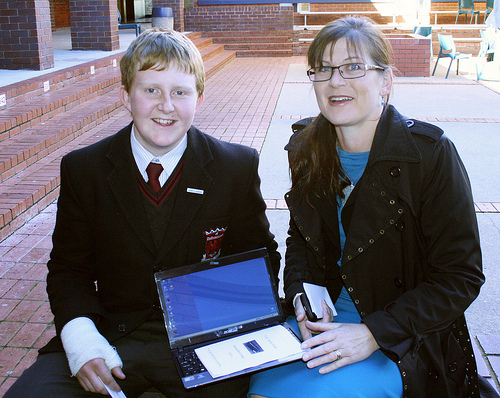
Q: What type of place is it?
A: It is a patio.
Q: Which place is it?
A: It is a patio.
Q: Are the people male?
A: No, they are both male and female.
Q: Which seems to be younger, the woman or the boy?
A: The boy is younger than the woman.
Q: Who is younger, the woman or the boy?
A: The boy is younger than the woman.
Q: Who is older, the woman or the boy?
A: The woman is older than the boy.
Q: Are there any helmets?
A: No, there are no helmets.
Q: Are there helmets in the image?
A: No, there are no helmets.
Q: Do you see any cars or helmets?
A: No, there are no helmets or cars.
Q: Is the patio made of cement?
A: Yes, the patio is made of cement.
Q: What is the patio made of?
A: The patio is made of concrete.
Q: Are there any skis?
A: No, there are no skis.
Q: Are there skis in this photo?
A: No, there are no skis.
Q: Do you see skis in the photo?
A: No, there are no skis.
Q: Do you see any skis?
A: No, there are no skis.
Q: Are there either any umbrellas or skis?
A: No, there are no skis or umbrellas.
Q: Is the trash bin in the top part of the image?
A: Yes, the trash bin is in the top of the image.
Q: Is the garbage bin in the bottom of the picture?
A: No, the garbage bin is in the top of the image.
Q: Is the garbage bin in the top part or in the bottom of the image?
A: The garbage bin is in the top of the image.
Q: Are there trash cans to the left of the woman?
A: Yes, there is a trash can to the left of the woman.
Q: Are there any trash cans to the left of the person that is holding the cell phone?
A: Yes, there is a trash can to the left of the woman.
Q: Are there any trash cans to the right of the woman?
A: No, the trash can is to the left of the woman.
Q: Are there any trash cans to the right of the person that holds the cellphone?
A: No, the trash can is to the left of the woman.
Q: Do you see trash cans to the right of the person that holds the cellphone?
A: No, the trash can is to the left of the woman.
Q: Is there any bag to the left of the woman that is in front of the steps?
A: No, there is a trash can to the left of the woman.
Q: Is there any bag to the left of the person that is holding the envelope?
A: No, there is a trash can to the left of the woman.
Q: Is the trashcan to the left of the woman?
A: Yes, the trashcan is to the left of the woman.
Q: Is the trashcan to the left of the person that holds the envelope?
A: Yes, the trashcan is to the left of the woman.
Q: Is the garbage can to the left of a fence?
A: No, the garbage can is to the left of the woman.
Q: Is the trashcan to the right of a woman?
A: No, the trashcan is to the left of a woman.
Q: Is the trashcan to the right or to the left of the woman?
A: The trashcan is to the left of the woman.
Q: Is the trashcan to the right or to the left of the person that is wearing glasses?
A: The trashcan is to the left of the woman.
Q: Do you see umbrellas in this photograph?
A: No, there are no umbrellas.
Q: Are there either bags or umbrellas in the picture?
A: No, there are no umbrellas or bags.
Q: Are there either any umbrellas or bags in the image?
A: No, there are no umbrellas or bags.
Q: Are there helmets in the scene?
A: No, there are no helmets.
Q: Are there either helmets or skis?
A: No, there are no helmets or skis.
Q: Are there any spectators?
A: No, there are no spectators.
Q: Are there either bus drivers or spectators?
A: No, there are no spectators or bus drivers.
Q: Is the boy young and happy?
A: Yes, the boy is young and happy.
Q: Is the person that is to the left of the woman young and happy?
A: Yes, the boy is young and happy.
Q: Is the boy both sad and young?
A: No, the boy is young but happy.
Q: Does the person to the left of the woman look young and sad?
A: No, the boy is young but happy.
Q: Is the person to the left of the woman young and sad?
A: No, the boy is young but happy.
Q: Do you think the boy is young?
A: Yes, the boy is young.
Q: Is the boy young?
A: Yes, the boy is young.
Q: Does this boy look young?
A: Yes, the boy is young.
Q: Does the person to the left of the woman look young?
A: Yes, the boy is young.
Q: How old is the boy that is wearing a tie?
A: The boy is young.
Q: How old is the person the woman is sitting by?
A: The boy is young.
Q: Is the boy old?
A: No, the boy is young.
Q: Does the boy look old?
A: No, the boy is young.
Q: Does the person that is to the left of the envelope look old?
A: No, the boy is young.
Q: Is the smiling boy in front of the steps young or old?
A: The boy is young.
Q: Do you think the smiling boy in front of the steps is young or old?
A: The boy is young.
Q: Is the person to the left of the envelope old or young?
A: The boy is young.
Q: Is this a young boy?
A: Yes, this is a young boy.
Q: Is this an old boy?
A: No, this is a young boy.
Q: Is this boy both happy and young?
A: Yes, the boy is happy and young.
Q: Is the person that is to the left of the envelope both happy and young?
A: Yes, the boy is happy and young.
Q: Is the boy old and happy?
A: No, the boy is happy but young.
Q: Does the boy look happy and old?
A: No, the boy is happy but young.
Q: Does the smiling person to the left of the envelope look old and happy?
A: No, the boy is happy but young.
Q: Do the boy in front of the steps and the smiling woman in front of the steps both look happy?
A: Yes, both the boy and the woman are happy.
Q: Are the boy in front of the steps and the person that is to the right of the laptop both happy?
A: Yes, both the boy and the woman are happy.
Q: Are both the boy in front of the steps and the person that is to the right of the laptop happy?
A: Yes, both the boy and the woman are happy.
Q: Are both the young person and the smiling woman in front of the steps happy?
A: Yes, both the boy and the woman are happy.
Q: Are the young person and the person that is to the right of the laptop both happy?
A: Yes, both the boy and the woman are happy.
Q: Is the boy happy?
A: Yes, the boy is happy.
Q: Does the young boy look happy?
A: Yes, the boy is happy.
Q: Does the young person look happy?
A: Yes, the boy is happy.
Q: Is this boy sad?
A: No, the boy is happy.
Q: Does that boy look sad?
A: No, the boy is happy.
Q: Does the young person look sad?
A: No, the boy is happy.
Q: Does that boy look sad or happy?
A: The boy is happy.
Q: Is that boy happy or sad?
A: The boy is happy.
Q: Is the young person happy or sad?
A: The boy is happy.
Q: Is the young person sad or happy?
A: The boy is happy.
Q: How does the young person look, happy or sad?
A: The boy is happy.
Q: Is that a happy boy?
A: Yes, that is a happy boy.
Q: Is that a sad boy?
A: No, that is a happy boy.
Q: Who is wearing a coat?
A: The boy is wearing a coat.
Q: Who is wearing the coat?
A: The boy is wearing a coat.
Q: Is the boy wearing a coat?
A: Yes, the boy is wearing a coat.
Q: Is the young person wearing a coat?
A: Yes, the boy is wearing a coat.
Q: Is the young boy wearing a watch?
A: No, the boy is wearing a coat.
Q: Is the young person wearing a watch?
A: No, the boy is wearing a coat.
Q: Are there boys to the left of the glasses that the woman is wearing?
A: Yes, there is a boy to the left of the glasses.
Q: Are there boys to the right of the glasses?
A: No, the boy is to the left of the glasses.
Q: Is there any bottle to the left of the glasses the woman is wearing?
A: No, there is a boy to the left of the glasses.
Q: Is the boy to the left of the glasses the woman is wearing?
A: Yes, the boy is to the left of the glasses.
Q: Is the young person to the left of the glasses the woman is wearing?
A: Yes, the boy is to the left of the glasses.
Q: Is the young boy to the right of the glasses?
A: No, the boy is to the left of the glasses.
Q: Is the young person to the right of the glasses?
A: No, the boy is to the left of the glasses.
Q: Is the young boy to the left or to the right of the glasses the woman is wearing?
A: The boy is to the left of the glasses.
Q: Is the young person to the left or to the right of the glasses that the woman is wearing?
A: The boy is to the left of the glasses.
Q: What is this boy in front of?
A: The boy is in front of the steps.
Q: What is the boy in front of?
A: The boy is in front of the steps.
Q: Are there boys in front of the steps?
A: Yes, there is a boy in front of the steps.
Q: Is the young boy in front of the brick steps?
A: Yes, the boy is in front of the steps.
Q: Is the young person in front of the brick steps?
A: Yes, the boy is in front of the steps.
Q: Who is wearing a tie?
A: The boy is wearing a tie.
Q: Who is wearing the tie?
A: The boy is wearing a tie.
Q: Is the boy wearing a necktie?
A: Yes, the boy is wearing a necktie.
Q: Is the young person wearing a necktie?
A: Yes, the boy is wearing a necktie.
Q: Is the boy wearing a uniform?
A: No, the boy is wearing a necktie.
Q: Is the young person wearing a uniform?
A: No, the boy is wearing a necktie.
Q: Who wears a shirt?
A: The boy wears a shirt.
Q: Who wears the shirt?
A: The boy wears a shirt.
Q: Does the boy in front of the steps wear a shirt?
A: Yes, the boy wears a shirt.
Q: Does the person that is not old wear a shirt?
A: Yes, the boy wears a shirt.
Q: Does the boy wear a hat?
A: No, the boy wears a shirt.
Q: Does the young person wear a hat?
A: No, the boy wears a shirt.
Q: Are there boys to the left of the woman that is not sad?
A: Yes, there is a boy to the left of the woman.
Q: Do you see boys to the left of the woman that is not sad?
A: Yes, there is a boy to the left of the woman.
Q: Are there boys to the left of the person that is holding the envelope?
A: Yes, there is a boy to the left of the woman.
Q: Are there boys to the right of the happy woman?
A: No, the boy is to the left of the woman.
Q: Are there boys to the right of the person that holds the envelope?
A: No, the boy is to the left of the woman.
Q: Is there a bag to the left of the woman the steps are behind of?
A: No, there is a boy to the left of the woman.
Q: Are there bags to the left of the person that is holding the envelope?
A: No, there is a boy to the left of the woman.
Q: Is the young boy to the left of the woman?
A: Yes, the boy is to the left of the woman.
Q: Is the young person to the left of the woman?
A: Yes, the boy is to the left of the woman.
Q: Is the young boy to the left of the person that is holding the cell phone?
A: Yes, the boy is to the left of the woman.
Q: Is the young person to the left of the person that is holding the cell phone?
A: Yes, the boy is to the left of the woman.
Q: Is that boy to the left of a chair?
A: No, the boy is to the left of the woman.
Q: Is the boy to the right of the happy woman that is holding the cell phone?
A: No, the boy is to the left of the woman.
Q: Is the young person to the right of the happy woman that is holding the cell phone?
A: No, the boy is to the left of the woman.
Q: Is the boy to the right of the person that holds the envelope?
A: No, the boy is to the left of the woman.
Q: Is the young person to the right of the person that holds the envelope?
A: No, the boy is to the left of the woman.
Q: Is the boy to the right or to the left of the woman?
A: The boy is to the left of the woman.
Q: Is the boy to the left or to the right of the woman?
A: The boy is to the left of the woman.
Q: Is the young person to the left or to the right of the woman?
A: The boy is to the left of the woman.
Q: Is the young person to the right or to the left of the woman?
A: The boy is to the left of the woman.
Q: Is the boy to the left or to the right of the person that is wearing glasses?
A: The boy is to the left of the woman.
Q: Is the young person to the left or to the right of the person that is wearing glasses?
A: The boy is to the left of the woman.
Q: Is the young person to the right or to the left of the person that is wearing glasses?
A: The boy is to the left of the woman.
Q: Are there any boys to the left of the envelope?
A: Yes, there is a boy to the left of the envelope.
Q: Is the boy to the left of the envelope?
A: Yes, the boy is to the left of the envelope.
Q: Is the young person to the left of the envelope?
A: Yes, the boy is to the left of the envelope.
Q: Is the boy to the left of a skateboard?
A: No, the boy is to the left of the envelope.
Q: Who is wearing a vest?
A: The boy is wearing a vest.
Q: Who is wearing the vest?
A: The boy is wearing a vest.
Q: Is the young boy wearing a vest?
A: Yes, the boy is wearing a vest.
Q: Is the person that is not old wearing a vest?
A: Yes, the boy is wearing a vest.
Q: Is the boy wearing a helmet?
A: No, the boy is wearing a vest.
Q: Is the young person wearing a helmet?
A: No, the boy is wearing a vest.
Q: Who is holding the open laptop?
A: The boy is holding the laptop.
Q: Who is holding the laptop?
A: The boy is holding the laptop.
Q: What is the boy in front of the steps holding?
A: The boy is holding the laptop.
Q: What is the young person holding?
A: The boy is holding the laptop.